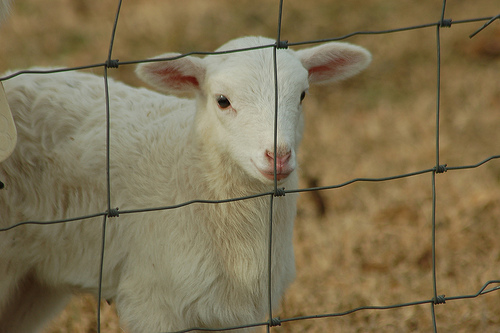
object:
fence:
[0, 0, 500, 333]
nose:
[261, 145, 293, 170]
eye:
[210, 91, 235, 110]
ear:
[136, 52, 203, 92]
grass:
[0, 0, 500, 333]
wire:
[428, 1, 446, 333]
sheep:
[0, 33, 375, 333]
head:
[135, 36, 371, 178]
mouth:
[245, 157, 307, 187]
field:
[0, 0, 499, 332]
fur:
[105, 175, 273, 282]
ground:
[0, 0, 499, 333]